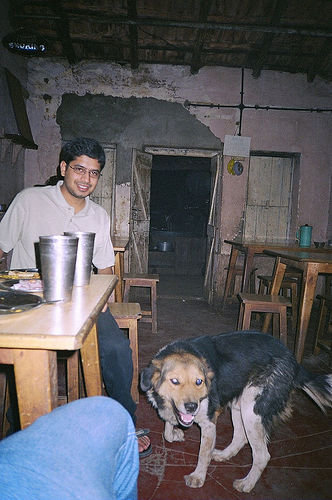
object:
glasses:
[65, 161, 103, 178]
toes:
[138, 435, 151, 452]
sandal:
[135, 427, 153, 459]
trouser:
[0, 395, 140, 500]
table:
[0, 272, 120, 431]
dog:
[140, 329, 332, 493]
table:
[261, 249, 331, 366]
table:
[219, 239, 331, 331]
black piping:
[185, 68, 332, 137]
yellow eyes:
[170, 377, 203, 386]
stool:
[237, 292, 293, 346]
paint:
[56, 90, 225, 186]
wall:
[0, 55, 332, 316]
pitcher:
[296, 223, 313, 248]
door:
[128, 147, 152, 302]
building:
[0, 0, 332, 305]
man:
[0, 136, 153, 460]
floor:
[128, 277, 332, 500]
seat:
[237, 292, 293, 307]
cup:
[38, 235, 79, 303]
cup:
[63, 230, 96, 286]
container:
[296, 224, 313, 249]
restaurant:
[0, 0, 332, 500]